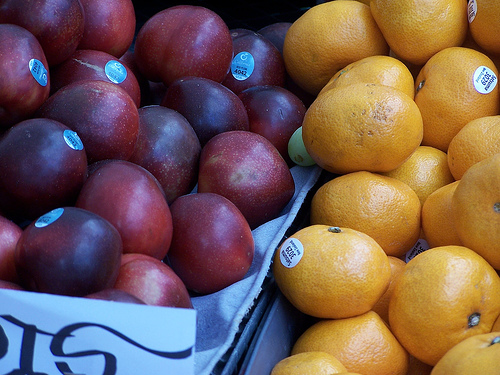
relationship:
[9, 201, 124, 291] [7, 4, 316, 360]
plum in crate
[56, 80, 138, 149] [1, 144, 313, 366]
red plum in crate